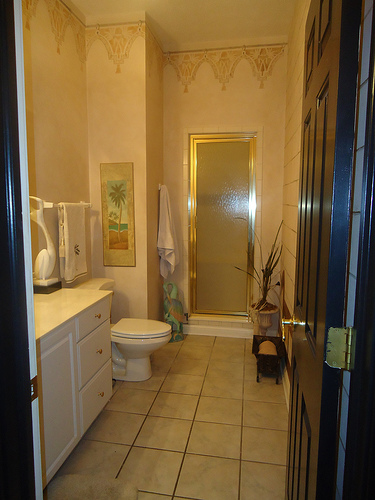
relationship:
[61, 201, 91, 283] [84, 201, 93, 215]
towel hanging on a wall hook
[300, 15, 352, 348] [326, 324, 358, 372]
bathroom door has hinges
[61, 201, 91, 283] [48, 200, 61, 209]
towel on a bar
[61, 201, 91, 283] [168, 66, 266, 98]
towel hanging on wall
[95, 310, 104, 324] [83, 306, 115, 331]
handles on drawer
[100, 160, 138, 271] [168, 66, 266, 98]
picture on wall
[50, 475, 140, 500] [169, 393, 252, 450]
bathroom rug on floor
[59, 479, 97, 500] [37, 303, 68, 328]
rug in front of counter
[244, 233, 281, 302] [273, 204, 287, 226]
plant in corner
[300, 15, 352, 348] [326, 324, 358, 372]
bathroom door has a hinges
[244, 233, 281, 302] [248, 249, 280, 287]
plant in a pot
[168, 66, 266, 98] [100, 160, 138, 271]
wall has a picture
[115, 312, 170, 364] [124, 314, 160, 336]
toilet has a cover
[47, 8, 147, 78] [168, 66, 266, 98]
decorations on wall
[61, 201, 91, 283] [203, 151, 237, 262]
towel hangs near mirror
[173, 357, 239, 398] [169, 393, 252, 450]
tiles on floor